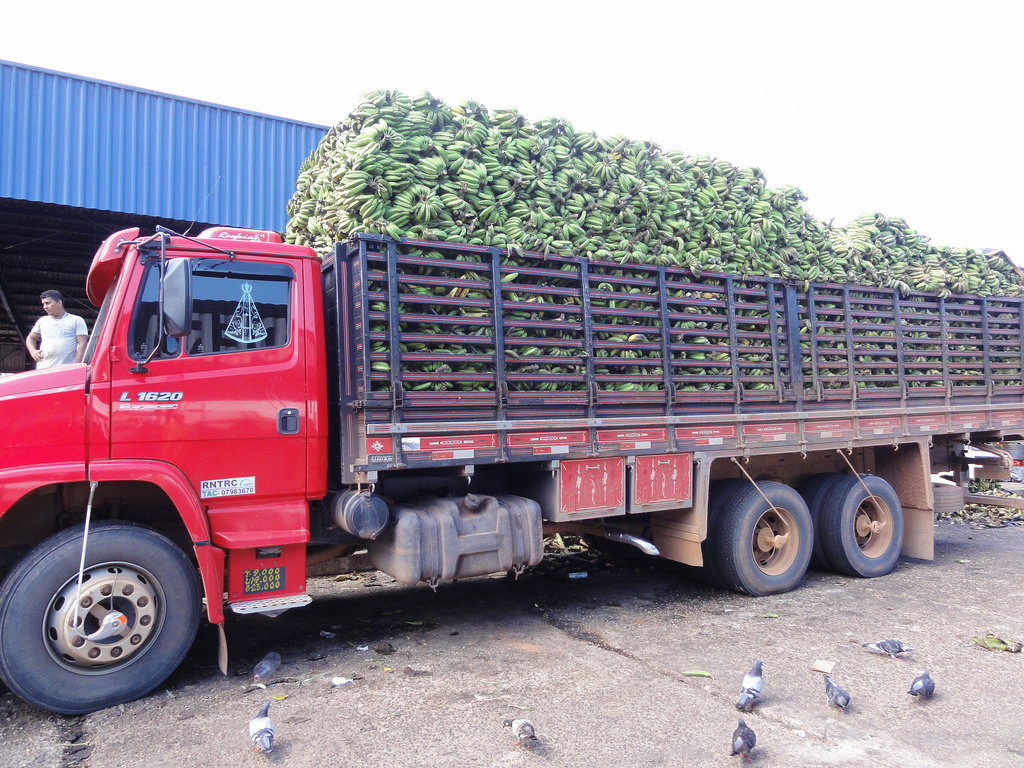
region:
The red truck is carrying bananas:
[27, 59, 999, 645]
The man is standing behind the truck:
[14, 231, 502, 703]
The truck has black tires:
[11, 95, 957, 713]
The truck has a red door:
[29, 148, 568, 746]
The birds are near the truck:
[294, 187, 816, 764]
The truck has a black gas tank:
[248, 148, 629, 668]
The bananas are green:
[296, 67, 680, 397]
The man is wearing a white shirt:
[241, 582, 264, 625]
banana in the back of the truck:
[731, 309, 821, 358]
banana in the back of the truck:
[899, 241, 939, 299]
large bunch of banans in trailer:
[269, 77, 1022, 433]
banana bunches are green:
[263, 84, 1022, 414]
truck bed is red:
[4, 216, 349, 728]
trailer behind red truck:
[303, 224, 1022, 621]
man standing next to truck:
[14, 284, 95, 374]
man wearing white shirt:
[30, 311, 89, 370]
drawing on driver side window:
[218, 273, 276, 362]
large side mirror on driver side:
[145, 249, 202, 344]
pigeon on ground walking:
[727, 709, 769, 760]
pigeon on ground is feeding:
[496, 709, 550, 755]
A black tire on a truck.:
[0, 512, 200, 715]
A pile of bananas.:
[277, 86, 1021, 404]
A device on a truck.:
[385, 485, 541, 585]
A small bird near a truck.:
[717, 717, 757, 763]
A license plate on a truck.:
[243, 551, 291, 600]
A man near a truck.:
[24, 279, 91, 369]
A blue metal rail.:
[318, 231, 1018, 419]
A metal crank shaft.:
[376, 487, 547, 586]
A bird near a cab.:
[246, 696, 281, 763]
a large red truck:
[0, 196, 1020, 712]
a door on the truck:
[141, 249, 307, 488]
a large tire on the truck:
[34, 534, 186, 684]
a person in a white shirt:
[28, 284, 80, 358]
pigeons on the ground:
[236, 655, 949, 729]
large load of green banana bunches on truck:
[281, 83, 1022, 410]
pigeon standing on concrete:
[246, 693, 286, 760]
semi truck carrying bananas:
[0, 92, 1023, 713]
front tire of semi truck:
[0, 518, 203, 716]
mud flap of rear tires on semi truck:
[879, 442, 937, 564]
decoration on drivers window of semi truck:
[221, 275, 270, 348]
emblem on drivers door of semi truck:
[114, 386, 185, 406]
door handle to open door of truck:
[272, 402, 304, 437]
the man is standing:
[26, 287, 90, 370]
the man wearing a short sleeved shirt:
[23, 285, 87, 369]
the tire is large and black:
[0, 521, 203, 722]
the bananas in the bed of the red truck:
[1, 88, 1020, 719]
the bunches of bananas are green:
[282, 86, 1022, 400]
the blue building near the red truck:
[1, 54, 1022, 712]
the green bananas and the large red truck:
[1, 86, 1022, 722]